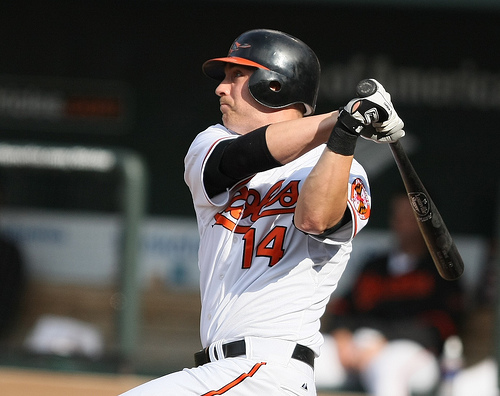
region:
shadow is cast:
[205, 178, 314, 268]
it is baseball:
[13, 13, 498, 347]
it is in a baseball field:
[22, 41, 474, 393]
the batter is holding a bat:
[1, 57, 441, 394]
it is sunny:
[8, 55, 480, 394]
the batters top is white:
[56, 78, 420, 395]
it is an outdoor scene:
[12, 57, 468, 393]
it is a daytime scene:
[24, 61, 455, 393]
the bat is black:
[130, 51, 410, 394]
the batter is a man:
[139, 58, 437, 392]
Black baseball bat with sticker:
[356, 72, 469, 290]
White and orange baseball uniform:
[173, 132, 350, 394]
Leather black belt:
[192, 332, 329, 369]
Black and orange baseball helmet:
[196, 16, 327, 113]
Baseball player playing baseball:
[122, 11, 469, 394]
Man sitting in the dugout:
[374, 170, 489, 395]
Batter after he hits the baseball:
[49, 6, 474, 393]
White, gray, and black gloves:
[336, 67, 412, 150]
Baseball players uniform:
[195, 137, 325, 392]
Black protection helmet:
[222, 33, 319, 106]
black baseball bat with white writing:
[351, 71, 479, 277]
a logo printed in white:
[400, 177, 440, 222]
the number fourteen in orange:
[233, 216, 303, 276]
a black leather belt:
[184, 325, 330, 375]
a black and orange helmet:
[196, 20, 351, 122]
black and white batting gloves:
[331, 77, 410, 150]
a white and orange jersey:
[169, 100, 378, 345]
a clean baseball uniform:
[88, 107, 362, 394]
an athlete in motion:
[106, 9, 457, 394]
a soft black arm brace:
[186, 114, 309, 187]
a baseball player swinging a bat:
[172, 22, 465, 362]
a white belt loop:
[238, 331, 301, 359]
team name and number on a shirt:
[221, 185, 296, 277]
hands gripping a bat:
[344, 64, 416, 154]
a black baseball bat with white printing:
[408, 167, 445, 272]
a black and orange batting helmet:
[199, 19, 322, 111]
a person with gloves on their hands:
[331, 72, 401, 147]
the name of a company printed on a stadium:
[309, 37, 495, 105]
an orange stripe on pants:
[210, 361, 253, 394]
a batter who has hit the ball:
[102, 28, 467, 393]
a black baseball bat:
[351, 71, 470, 286]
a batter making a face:
[121, 31, 412, 393]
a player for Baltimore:
[111, 19, 422, 393]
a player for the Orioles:
[131, 27, 383, 394]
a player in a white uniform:
[112, 30, 412, 392]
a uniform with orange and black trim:
[118, 28, 401, 394]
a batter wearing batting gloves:
[81, 26, 423, 394]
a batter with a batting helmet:
[81, 28, 411, 394]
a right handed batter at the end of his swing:
[91, 41, 486, 393]